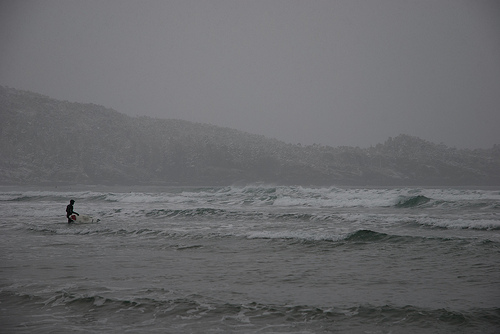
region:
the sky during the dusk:
[210, 32, 371, 123]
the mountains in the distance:
[44, 88, 105, 145]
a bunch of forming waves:
[345, 183, 385, 203]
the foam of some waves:
[204, 182, 224, 200]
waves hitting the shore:
[64, 278, 112, 325]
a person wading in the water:
[55, 189, 99, 231]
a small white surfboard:
[62, 203, 93, 228]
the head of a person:
[67, 196, 75, 206]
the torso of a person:
[62, 205, 74, 212]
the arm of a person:
[70, 211, 81, 218]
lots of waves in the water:
[145, 185, 425, 298]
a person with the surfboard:
[57, 192, 92, 232]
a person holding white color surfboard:
[67, 207, 94, 227]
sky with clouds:
[52, 8, 407, 79]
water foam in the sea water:
[291, 173, 381, 213]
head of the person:
[63, 198, 80, 207]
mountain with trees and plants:
[110, 102, 330, 186]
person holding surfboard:
[64, 214, 84, 226]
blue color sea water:
[148, 221, 422, 320]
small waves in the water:
[204, 242, 354, 319]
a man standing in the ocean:
[60, 196, 104, 233]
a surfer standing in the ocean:
[60, 192, 90, 229]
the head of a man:
[67, 194, 74, 206]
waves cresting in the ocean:
[212, 180, 456, 215]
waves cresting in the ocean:
[128, 202, 377, 247]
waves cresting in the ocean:
[374, 185, 480, 207]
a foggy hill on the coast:
[34, 79, 490, 191]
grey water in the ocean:
[74, 264, 385, 332]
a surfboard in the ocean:
[65, 212, 105, 228]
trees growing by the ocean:
[120, 134, 305, 183]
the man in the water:
[60, 190, 85, 227]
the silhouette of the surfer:
[60, 195, 81, 215]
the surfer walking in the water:
[52, 197, 80, 228]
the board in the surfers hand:
[62, 194, 94, 236]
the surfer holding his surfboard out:
[63, 192, 102, 226]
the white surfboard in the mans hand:
[67, 211, 99, 224]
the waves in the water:
[155, 178, 499, 213]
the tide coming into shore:
[57, 283, 496, 323]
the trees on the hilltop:
[300, 130, 497, 154]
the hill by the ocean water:
[0, 80, 231, 175]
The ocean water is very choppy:
[143, 174, 465, 324]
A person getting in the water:
[58, 191, 119, 232]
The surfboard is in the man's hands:
[67, 210, 104, 225]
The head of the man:
[66, 195, 80, 207]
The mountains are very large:
[13, 87, 468, 180]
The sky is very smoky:
[76, 19, 454, 110]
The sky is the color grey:
[57, 21, 491, 109]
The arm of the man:
[68, 204, 82, 217]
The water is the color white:
[281, 184, 399, 207]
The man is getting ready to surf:
[19, 172, 125, 248]